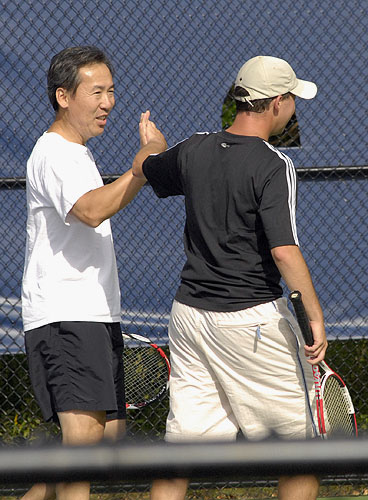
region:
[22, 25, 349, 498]
Two men giving "high five" sign.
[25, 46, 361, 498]
Two men carrying tennis rackets.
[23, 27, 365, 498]
Two men on a tennis court.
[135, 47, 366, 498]
The man on the right is wearing a tan baseball cap.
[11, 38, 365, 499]
The two men are touching.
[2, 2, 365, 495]
A metal fence behind the men.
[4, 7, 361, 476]
blue screen behind chain-link fence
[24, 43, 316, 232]
tennis players touching each other's palms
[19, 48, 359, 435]
players holding tennis rackets below their waists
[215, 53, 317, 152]
head in front of cutout in screen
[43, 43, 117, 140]
man smiling with teeth showing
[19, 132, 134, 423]
white t-shirt over black shorts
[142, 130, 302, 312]
black shirt with white stripes down sleeves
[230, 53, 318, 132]
man wearing tan cap on head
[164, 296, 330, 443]
zippered pocket on back of white shorts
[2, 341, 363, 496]
plants growing on other side of fence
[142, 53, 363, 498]
man high fiving after game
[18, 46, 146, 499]
man high fiving after game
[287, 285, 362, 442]
man holding red and white racket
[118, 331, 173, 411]
man holding red and white racket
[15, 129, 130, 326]
white shirt on the tennis player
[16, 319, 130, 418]
black shorts on the tennis player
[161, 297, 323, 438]
white shorts on the tennis player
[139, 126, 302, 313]
black shirt on the tennis player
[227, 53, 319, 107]
white hat on the tennis player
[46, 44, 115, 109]
black hair on the tennis player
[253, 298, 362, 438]
The man is holding a racket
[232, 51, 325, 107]
The man is wearing a cap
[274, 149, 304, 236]
White strips on the sleeve on the shirt.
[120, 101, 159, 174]
The two men is holding hands.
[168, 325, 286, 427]
The man is wearing tan shorts.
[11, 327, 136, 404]
The shorts is black.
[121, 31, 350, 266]
The wall behind the fence is blue.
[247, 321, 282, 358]
Zipper hanging from back pocket.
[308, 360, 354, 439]
The racket is white black and red.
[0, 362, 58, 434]
The grass is green.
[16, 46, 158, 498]
man is high fiving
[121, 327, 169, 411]
racket is red and black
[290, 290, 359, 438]
racket is red and black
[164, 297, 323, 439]
shorts are white and blue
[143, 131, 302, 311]
shirt is black with white stripes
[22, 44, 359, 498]
men are high fiving each other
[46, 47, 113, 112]
man has black hair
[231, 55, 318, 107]
man is wearing a cap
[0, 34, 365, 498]
fence is chain link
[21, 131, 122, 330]
shirt is white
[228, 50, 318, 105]
a man wearing a hat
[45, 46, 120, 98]
a man with black hair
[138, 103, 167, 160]
two men touching hands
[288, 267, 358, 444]
a man holding a tennis racket